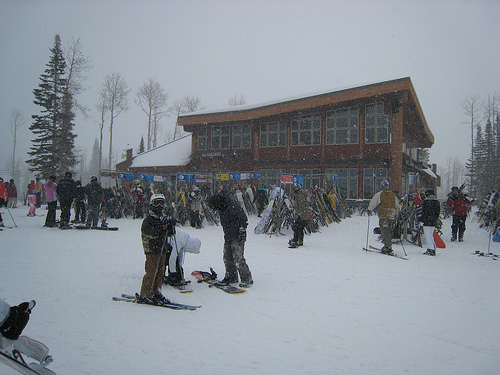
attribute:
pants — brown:
[136, 250, 171, 297]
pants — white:
[419, 223, 439, 259]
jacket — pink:
[41, 163, 62, 216]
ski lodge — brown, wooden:
[100, 74, 450, 229]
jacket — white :
[166, 228, 201, 272]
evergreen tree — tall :
[27, 32, 78, 174]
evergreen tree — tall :
[465, 123, 487, 209]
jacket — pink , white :
[42, 180, 59, 204]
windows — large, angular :
[193, 100, 393, 150]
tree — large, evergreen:
[23, 33, 80, 179]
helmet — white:
[147, 192, 167, 203]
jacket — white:
[162, 223, 230, 275]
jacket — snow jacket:
[163, 164, 284, 292]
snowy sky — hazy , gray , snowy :
[8, 7, 488, 139]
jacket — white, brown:
[367, 190, 404, 220]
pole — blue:
[172, 227, 192, 291]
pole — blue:
[146, 236, 173, 301]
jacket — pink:
[37, 178, 60, 203]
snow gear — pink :
[21, 196, 46, 212]